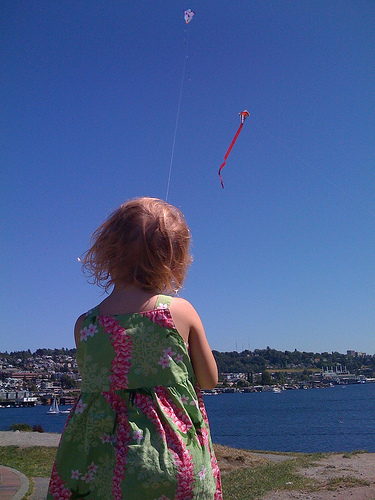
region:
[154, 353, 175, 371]
white flower on dress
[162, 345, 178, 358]
white flower on dress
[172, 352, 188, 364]
white flower on dress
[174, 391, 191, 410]
white flower on dress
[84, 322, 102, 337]
white flower on dress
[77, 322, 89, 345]
white flower on dress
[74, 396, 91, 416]
white flower on dress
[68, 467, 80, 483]
white flower on dress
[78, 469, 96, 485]
white flower on dress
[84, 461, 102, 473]
white flower on dress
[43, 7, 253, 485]
Child flying a kite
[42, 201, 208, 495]
Little girl wearing a green and pink dress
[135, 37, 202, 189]
String in front of child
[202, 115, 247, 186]
A red tail on the kite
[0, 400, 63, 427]
Seashore or harbour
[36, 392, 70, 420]
Sailboat in the harbour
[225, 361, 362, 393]
Buildings along the shore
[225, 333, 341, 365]
Tree line in the background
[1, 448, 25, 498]
A brick path or walkway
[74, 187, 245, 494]
a little girl flying a kite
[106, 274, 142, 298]
the neck of a little girl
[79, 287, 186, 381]
the back of a little girl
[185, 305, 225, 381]
the arm of a little girl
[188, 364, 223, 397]
the elbow of a little girl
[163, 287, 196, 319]
the shoulder of a little girl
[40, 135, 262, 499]
this is a little girl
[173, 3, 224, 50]
this is a kite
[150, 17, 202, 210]
string attached to kite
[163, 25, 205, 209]
string attached to kite is white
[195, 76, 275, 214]
this a red kite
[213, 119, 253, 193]
red tail on kite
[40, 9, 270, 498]
the girl is flying a kite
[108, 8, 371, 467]
kites flying over water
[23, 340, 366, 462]
water is dark blue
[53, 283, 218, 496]
girl wearing floral print dress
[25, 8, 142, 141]
The sky is clear and blue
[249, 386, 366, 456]
The water is very calm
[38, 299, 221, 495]
The girl is wearing a floral dress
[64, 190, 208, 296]
The girl has blonde hair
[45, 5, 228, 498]
The girl is flying her kite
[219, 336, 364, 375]
The trees are on the mountain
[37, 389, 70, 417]
The boat on the water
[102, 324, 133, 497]
The dress has pink flowers on it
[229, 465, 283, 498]
The grass is short and green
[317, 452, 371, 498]
The dirt is the color brown